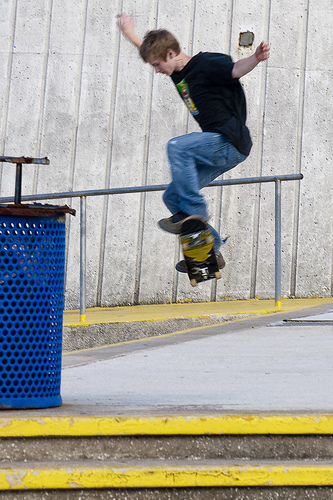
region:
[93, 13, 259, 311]
A boy on a skate board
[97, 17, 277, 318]
A boy on a skate board in the air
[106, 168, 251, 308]
a skate board in the air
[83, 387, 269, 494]
two yellow concrete steps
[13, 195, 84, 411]
a blue mesh trash can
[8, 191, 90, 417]
a blue metal trash can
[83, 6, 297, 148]
A boy with his arms out stretched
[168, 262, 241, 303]
Rear wheels on a skate board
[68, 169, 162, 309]
A metal railing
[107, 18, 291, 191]
A boy in a black shirt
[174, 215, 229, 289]
skateboard that the man is doing the stunt on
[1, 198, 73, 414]
blue garbage can at the side of the steps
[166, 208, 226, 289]
skateboard that is gold and black on the bottom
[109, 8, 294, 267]
the man doing a skateboard stunt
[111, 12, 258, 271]
the man is wearing blue jeans and a black tee shirt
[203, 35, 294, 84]
his arm is stretched straight out to help hold his balance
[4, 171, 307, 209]
the metal railing can be used by skateboarders for grinding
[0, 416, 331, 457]
the step is yellow and can be used for jumps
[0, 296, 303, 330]
the ramp can be used to getting speed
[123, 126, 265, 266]
the mans jeans have a hole in the knee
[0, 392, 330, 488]
The steps are yellow.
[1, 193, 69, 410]
The trash can is blue.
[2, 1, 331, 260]
The wall is grey.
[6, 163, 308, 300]
The hand rail is blue.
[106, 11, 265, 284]
The boy is skateboarding.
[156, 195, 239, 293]
The skateboard is in the air.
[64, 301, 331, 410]
The ground is grey.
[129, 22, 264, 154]
The boy's shirt is black.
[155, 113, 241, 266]
The boy's shorts are blue.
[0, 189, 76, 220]
The trash bag is black.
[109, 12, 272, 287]
a boy is getting air on the skateboard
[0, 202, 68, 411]
a blue trash can is on the sidewalk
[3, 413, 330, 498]
the steps have a yellow stripe on them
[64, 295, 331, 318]
the sidewalk is painted yellow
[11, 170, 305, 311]
a steel railing is next to the sidewalk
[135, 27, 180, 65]
the boy has brown hair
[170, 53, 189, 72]
the boy has a tattoo on his neck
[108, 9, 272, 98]
both arms are in the air on the boy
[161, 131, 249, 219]
the boy is wearing torn blue jeans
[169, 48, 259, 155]
the kid is wearing a black t-shirt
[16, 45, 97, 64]
faint line on the wall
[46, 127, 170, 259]
deep groove horizontal lines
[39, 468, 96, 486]
chipped spot on yellow paint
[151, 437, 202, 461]
white spots on pavement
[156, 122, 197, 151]
white spot on blue jeans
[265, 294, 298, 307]
yellow paint at bottom of blue post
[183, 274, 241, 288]
tan wheels on black skate board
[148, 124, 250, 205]
man wearing faded blue jeans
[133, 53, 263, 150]
black shirt with logo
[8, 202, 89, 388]
blue wire mesh trash can